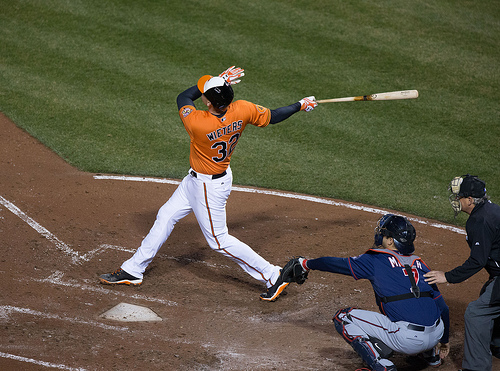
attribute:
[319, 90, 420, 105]
bat — brow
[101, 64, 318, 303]
batters — swinging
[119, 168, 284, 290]
pants — white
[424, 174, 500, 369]
umpire — leaning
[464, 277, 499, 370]
pants — gray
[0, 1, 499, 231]
grass — green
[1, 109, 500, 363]
ball field — brown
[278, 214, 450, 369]
catcher — squatting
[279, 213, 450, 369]
player — crouched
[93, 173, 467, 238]
line — white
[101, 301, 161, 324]
home plate — white